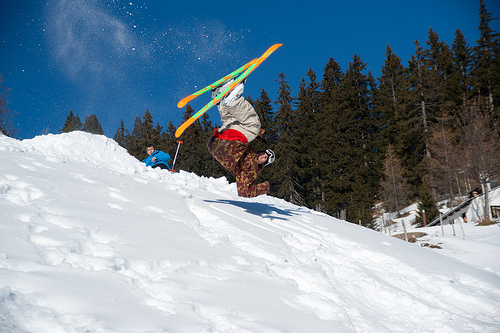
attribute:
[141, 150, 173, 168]
jacket — blue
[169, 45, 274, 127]
skis — green, orange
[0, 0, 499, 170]
sky — blue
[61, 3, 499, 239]
trees — tall, green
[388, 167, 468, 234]
house — small, white